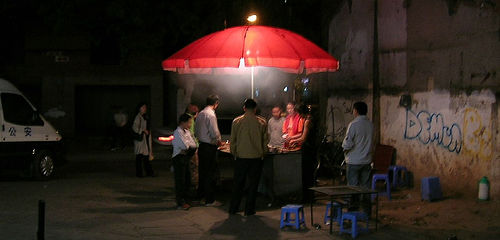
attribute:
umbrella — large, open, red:
[163, 25, 342, 101]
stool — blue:
[279, 203, 308, 232]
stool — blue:
[339, 211, 369, 239]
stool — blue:
[322, 199, 352, 225]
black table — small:
[307, 184, 381, 234]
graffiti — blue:
[402, 106, 463, 154]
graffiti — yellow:
[461, 109, 494, 161]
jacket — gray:
[342, 114, 375, 165]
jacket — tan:
[230, 109, 269, 160]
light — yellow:
[246, 14, 257, 26]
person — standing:
[196, 92, 223, 207]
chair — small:
[371, 174, 393, 202]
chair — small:
[386, 165, 408, 190]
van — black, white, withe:
[2, 74, 69, 183]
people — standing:
[173, 91, 318, 216]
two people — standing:
[282, 101, 315, 202]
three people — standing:
[268, 100, 318, 203]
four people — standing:
[171, 94, 260, 217]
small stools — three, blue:
[281, 198, 372, 239]